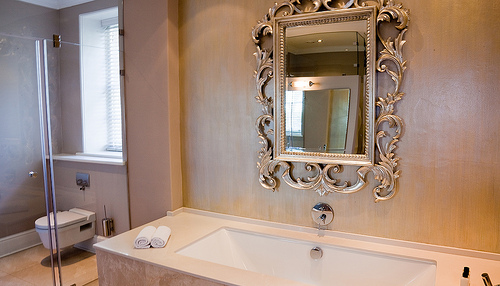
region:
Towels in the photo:
[135, 222, 175, 254]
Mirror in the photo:
[280, 42, 362, 159]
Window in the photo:
[77, 26, 127, 145]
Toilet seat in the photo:
[35, 203, 92, 252]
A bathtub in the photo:
[225, 224, 360, 282]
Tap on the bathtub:
[306, 237, 341, 266]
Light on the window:
[62, 37, 127, 128]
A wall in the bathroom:
[4, 59, 42, 153]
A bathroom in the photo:
[20, 57, 442, 284]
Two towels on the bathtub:
[131, 210, 173, 254]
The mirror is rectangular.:
[268, 13, 378, 163]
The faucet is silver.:
[300, 206, 335, 227]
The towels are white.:
[125, 213, 172, 252]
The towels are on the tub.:
[126, 219, 171, 249]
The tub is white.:
[167, 220, 429, 284]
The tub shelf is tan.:
[90, 195, 490, 283]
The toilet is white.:
[30, 207, 101, 244]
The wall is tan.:
[135, 5, 498, 252]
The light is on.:
[286, 73, 320, 88]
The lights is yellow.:
[290, 76, 315, 96]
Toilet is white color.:
[14, 200, 85, 257]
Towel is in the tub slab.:
[114, 217, 182, 262]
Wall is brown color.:
[137, 23, 248, 180]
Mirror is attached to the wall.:
[242, 10, 409, 195]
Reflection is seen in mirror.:
[276, 21, 383, 151]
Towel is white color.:
[127, 220, 191, 262]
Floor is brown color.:
[3, 245, 68, 285]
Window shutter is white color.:
[66, 15, 140, 161]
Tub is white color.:
[165, 193, 438, 284]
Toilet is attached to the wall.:
[27, 196, 110, 253]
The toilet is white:
[35, 207, 93, 249]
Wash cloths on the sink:
[133, 225, 168, 247]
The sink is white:
[177, 226, 437, 283]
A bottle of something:
[460, 266, 469, 284]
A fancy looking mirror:
[250, 3, 407, 197]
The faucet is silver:
[311, 203, 335, 227]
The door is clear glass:
[1, 34, 129, 284]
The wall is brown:
[125, 0, 499, 251]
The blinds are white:
[100, 21, 123, 152]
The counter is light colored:
[92, 206, 498, 284]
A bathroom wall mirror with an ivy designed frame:
[249, 0, 411, 204]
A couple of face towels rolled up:
[132, 224, 172, 251]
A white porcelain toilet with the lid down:
[33, 205, 97, 252]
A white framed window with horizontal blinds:
[75, 6, 123, 158]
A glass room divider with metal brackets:
[0, 0, 132, 285]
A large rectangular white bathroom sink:
[172, 224, 437, 284]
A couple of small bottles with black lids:
[458, 264, 472, 284]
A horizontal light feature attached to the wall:
[286, 79, 321, 89]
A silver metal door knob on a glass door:
[26, 167, 39, 180]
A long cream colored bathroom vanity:
[91, 204, 498, 285]